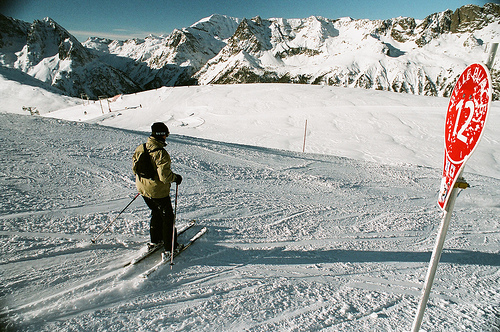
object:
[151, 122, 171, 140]
head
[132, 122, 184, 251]
man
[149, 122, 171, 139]
cap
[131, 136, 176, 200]
jacket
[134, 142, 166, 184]
backpack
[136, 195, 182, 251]
pants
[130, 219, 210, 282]
skis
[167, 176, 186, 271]
ski poles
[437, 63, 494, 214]
sign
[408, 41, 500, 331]
post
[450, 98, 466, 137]
number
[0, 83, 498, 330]
snow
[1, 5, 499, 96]
mountains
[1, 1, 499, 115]
background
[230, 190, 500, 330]
snow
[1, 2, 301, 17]
sky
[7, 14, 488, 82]
snow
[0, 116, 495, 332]
ground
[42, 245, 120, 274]
snow